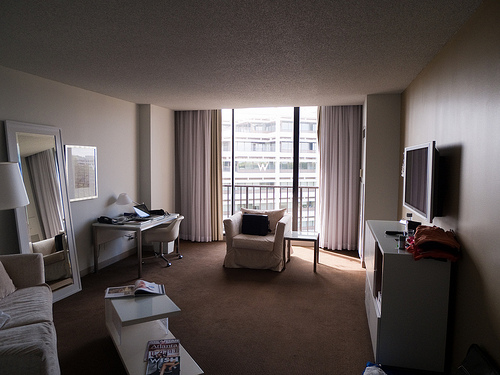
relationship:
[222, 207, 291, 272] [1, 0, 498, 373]
chair in middle of room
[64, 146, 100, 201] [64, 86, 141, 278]
picture hanging on wall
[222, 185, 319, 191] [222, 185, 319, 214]
rail on balcony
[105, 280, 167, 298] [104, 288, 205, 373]
magazine on coffee table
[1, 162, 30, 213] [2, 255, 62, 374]
lamp by side of chair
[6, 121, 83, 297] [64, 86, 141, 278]
mirror leaning on wall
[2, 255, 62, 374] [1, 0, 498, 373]
chair in room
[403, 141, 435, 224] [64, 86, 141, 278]
tv hanging on wall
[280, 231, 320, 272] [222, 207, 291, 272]
table by chair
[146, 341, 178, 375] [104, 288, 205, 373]
magazine on coffee table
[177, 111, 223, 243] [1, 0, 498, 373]
curtain in room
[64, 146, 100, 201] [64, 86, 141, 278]
picture on wall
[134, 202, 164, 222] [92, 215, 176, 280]
laptop on table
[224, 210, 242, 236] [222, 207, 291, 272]
arm of chair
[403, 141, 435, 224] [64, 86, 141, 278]
tv on wall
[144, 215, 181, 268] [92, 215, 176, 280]
chair at desk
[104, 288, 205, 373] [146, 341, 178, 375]
coffee table with magazine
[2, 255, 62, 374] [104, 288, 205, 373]
couch behind coffee table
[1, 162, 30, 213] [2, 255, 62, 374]
lamp by chair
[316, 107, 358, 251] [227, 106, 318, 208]
curtain on door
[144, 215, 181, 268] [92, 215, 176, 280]
chair under table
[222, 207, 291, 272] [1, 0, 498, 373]
chair in room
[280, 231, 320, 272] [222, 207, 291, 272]
table beside chair